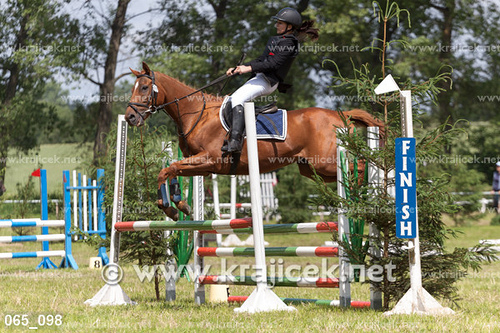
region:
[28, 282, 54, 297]
this is the grass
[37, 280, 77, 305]
the grass is green in color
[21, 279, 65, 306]
the grass is short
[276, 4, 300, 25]
this is a helmet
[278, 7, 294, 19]
the helmet is black in color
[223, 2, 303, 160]
this is a jockey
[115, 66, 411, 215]
this is a horse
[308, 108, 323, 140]
the fur is brown in color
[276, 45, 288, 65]
the coat is black in color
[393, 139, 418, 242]
this is a signboard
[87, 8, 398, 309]
horse jumping over fence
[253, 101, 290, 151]
blue blanket under saddle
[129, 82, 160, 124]
bridle on horse face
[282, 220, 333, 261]
red, white and green pole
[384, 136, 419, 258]
blue sign with white word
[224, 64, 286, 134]
white pants on horse rider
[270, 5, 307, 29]
black helmet on head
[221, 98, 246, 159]
black boot on rider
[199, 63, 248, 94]
reigns in riders hands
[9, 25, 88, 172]
green leaves on tree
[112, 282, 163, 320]
the field is lightgreen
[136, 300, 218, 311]
the field is lightgreen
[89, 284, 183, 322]
the field is lightgreen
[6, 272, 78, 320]
the field is lightgreen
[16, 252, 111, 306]
the field is lightgreen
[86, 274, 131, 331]
the field is lightgreen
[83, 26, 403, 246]
the horse is brown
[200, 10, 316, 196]
woman is leaning back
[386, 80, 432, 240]
the sign is blue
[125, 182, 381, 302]
the poles are striped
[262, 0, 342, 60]
woman wearing black helmet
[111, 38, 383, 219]
horse is in air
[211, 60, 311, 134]
woman's pants are white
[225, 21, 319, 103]
woman's jacket is black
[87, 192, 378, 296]
poles are green red and white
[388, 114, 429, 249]
white letters on sign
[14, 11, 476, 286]
the jockey competes in horse show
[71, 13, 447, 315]
the jockey jumps a hurdle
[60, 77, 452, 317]
the hurdle is tiered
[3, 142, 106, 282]
more hurdles in the background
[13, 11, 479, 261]
lots of trees and bushes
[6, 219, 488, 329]
lots of grass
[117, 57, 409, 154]
a blue saddle is on the horse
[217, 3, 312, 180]
the jockey is wearing white pants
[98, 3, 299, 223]
the jockey looks confident